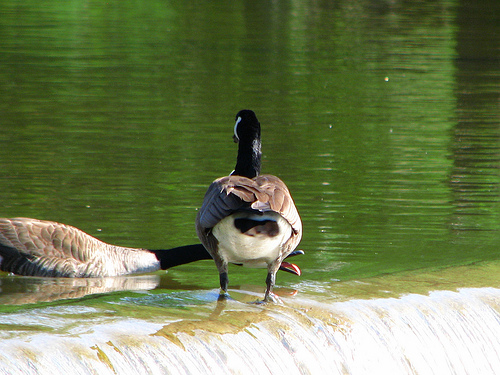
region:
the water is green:
[337, 286, 354, 313]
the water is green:
[335, 243, 350, 263]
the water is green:
[322, 330, 327, 332]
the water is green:
[339, 305, 359, 331]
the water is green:
[342, 312, 357, 324]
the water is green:
[332, 323, 347, 328]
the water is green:
[342, 326, 354, 339]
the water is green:
[342, 325, 345, 341]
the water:
[332, 148, 416, 361]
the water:
[307, 137, 328, 321]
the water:
[323, 205, 381, 357]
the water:
[403, 95, 428, 254]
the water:
[328, 62, 451, 364]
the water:
[294, 94, 381, 352]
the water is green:
[367, 291, 369, 316]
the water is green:
[337, 313, 353, 347]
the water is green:
[317, 345, 324, 358]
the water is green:
[392, 195, 399, 205]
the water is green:
[350, 273, 360, 295]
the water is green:
[354, 265, 365, 285]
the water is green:
[360, 220, 372, 249]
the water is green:
[363, 268, 380, 288]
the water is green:
[347, 271, 362, 281]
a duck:
[220, 94, 302, 372]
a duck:
[181, 86, 278, 335]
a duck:
[147, 132, 332, 361]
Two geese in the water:
[25, 89, 313, 293]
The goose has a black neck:
[219, 104, 281, 174]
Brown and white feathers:
[191, 163, 317, 263]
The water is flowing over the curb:
[68, 253, 480, 364]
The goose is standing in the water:
[186, 100, 317, 321]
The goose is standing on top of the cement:
[180, 103, 467, 339]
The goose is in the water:
[19, 178, 302, 326]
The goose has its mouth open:
[139, 226, 316, 290]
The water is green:
[161, 48, 411, 228]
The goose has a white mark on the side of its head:
[221, 106, 256, 140]